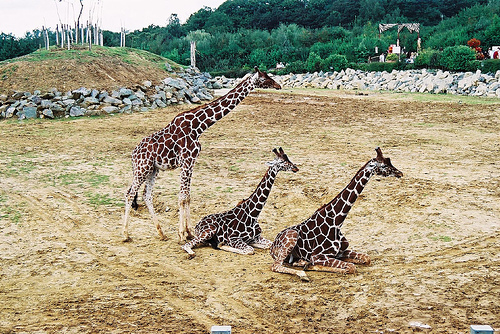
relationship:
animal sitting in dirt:
[268, 145, 404, 283] [0, 96, 482, 315]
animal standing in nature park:
[119, 63, 282, 243] [10, 2, 498, 323]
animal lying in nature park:
[179, 144, 299, 260] [10, 2, 498, 323]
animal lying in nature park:
[266, 145, 404, 281] [10, 2, 498, 323]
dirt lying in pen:
[272, 283, 433, 325] [1, 31, 484, 331]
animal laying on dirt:
[123, 66, 282, 243] [189, 252, 405, 317]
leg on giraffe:
[314, 257, 359, 273] [262, 150, 407, 282]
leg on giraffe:
[340, 249, 372, 262] [262, 150, 407, 282]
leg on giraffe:
[269, 259, 309, 282] [262, 150, 407, 282]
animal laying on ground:
[181, 147, 299, 261] [2, 95, 494, 331]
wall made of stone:
[213, 67, 498, 99] [208, 66, 495, 98]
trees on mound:
[27, 7, 120, 52] [1, 44, 213, 118]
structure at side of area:
[374, 16, 429, 78] [0, 42, 500, 332]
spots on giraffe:
[122, 67, 281, 202] [112, 64, 284, 245]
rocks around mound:
[5, 70, 220, 120] [1, 44, 213, 118]